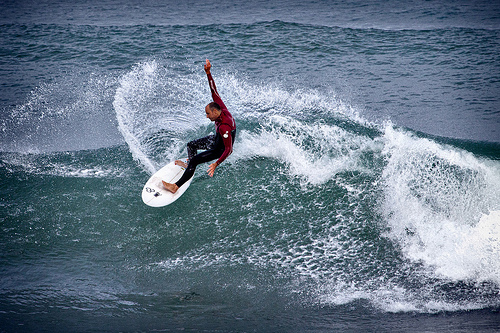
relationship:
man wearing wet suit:
[161, 57, 237, 194] [176, 74, 235, 186]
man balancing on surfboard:
[161, 57, 237, 194] [139, 157, 196, 208]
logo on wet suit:
[221, 129, 229, 140] [176, 74, 235, 186]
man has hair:
[161, 57, 237, 194] [209, 102, 221, 111]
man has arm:
[161, 57, 237, 194] [202, 57, 226, 108]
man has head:
[161, 57, 237, 194] [205, 102, 222, 122]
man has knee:
[161, 57, 237, 194] [186, 141, 197, 152]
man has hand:
[161, 57, 237, 194] [204, 162, 219, 177]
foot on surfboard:
[174, 155, 186, 171] [139, 157, 196, 208]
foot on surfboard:
[161, 179, 180, 193] [139, 157, 196, 208]